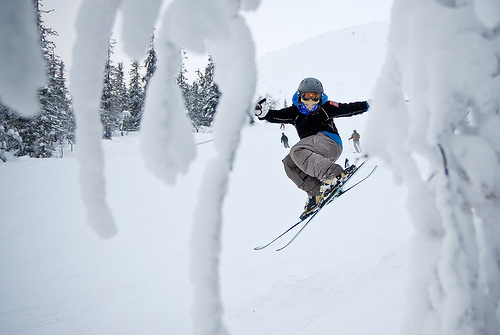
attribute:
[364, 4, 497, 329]
leaf — snowy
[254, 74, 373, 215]
skier — jumping, skiing, solo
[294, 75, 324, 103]
helmet — grey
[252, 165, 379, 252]
ski — long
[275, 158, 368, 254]
ski — long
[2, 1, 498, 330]
mountain — snowy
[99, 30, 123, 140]
tree — snowy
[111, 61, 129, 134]
tree — snowy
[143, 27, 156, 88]
tree — snowy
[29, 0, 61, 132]
tree — snowy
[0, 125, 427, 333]
snow — snowy, present, white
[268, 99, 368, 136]
jacket — black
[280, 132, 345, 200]
pants — tan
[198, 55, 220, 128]
tree — snowy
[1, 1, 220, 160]
trees — snowy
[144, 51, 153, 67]
branch — snowy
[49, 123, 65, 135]
branch — snowy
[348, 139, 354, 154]
pole — ski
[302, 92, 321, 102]
goggles — orange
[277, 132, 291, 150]
skier — distant